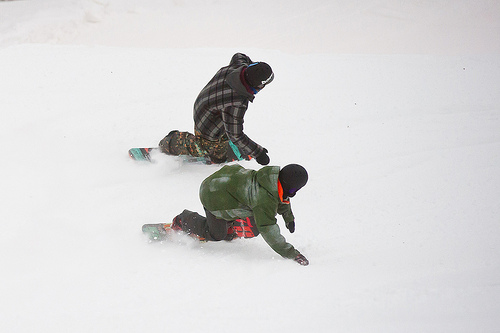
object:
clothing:
[197, 161, 300, 260]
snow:
[0, 0, 499, 332]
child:
[157, 51, 273, 165]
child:
[167, 162, 308, 265]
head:
[241, 61, 276, 90]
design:
[230, 216, 255, 239]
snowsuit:
[178, 163, 298, 260]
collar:
[273, 177, 289, 206]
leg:
[184, 212, 227, 244]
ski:
[141, 222, 179, 242]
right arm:
[249, 204, 295, 260]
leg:
[176, 131, 223, 164]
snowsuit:
[159, 51, 265, 166]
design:
[228, 141, 244, 162]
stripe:
[197, 102, 243, 131]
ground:
[0, 0, 499, 331]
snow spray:
[141, 224, 208, 252]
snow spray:
[139, 147, 182, 182]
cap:
[277, 163, 310, 197]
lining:
[278, 182, 288, 207]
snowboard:
[128, 147, 251, 166]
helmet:
[244, 61, 276, 89]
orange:
[278, 182, 282, 202]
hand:
[292, 249, 308, 266]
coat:
[190, 52, 264, 160]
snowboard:
[140, 223, 240, 243]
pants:
[174, 207, 258, 241]